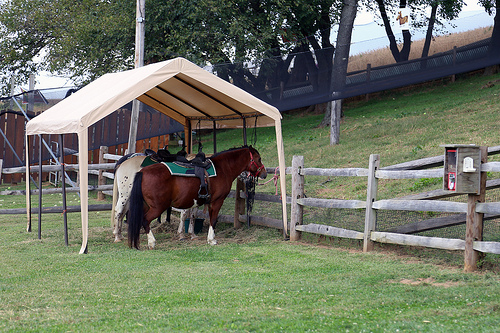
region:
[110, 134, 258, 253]
two horses under the shelter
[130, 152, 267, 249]
brown horse with white feet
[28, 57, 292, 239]
white shelter with black support structure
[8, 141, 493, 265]
wooden fence around the pasture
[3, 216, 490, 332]
grass pasture the horses are in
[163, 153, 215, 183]
green saddle on horse's back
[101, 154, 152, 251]
white horse with brown spots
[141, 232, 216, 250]
white feet of the horse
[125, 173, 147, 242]
black tail of the brown horse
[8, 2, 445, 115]
trees on the hillside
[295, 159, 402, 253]
a wooden fence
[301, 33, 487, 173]
a hill in a pasture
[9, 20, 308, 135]
the roof of a car port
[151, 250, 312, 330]
green grass in the pasture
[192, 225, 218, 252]
white feet on a horse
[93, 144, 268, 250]
two horses standing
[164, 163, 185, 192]
a green and white blanket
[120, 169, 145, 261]
black tail of horse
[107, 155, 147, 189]
a white and black horse rump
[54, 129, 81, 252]
a gray metal pole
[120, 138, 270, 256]
red horse standing under tent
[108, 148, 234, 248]
white horse standing under tent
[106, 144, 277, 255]
white horse standing be red horse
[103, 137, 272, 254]
red horse standing by white horse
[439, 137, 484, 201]
wood box on fence with red trim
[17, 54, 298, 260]
white tent over horses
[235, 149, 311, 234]
wood fence by white tent with horses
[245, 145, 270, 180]
red bridal on horse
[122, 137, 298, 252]
red horse tied to fence with rope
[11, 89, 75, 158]
black mesh screen beside white tent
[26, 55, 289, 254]
Horses uned a canopy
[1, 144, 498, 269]
Fences made of wood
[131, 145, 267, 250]
A brown horse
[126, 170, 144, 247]
The tail of a horse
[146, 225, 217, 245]
A horse with white feet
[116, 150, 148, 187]
The rear end of a horse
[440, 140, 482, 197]
A wooden box on a fence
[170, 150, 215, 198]
A horse saddle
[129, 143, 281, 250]
A horse tied to a fence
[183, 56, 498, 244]
A grassy slope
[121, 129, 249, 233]
two horses under tent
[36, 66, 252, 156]
tent has white canopy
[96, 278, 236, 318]
green and short grass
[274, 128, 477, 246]
grey and wooden fence